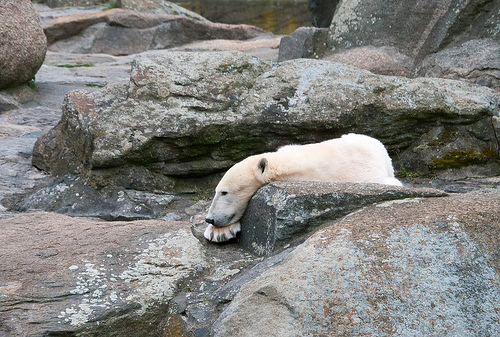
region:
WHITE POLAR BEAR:
[197, 127, 403, 244]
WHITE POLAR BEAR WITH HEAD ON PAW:
[179, 120, 404, 243]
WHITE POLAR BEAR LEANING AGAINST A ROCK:
[199, 131, 402, 246]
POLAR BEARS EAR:
[255, 156, 270, 176]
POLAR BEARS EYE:
[218, 189, 230, 197]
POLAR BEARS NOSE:
[205, 212, 213, 224]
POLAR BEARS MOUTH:
[219, 211, 237, 224]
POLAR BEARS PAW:
[204, 221, 244, 241]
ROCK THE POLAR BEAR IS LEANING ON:
[249, 178, 449, 254]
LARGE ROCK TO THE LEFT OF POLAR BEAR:
[31, 46, 498, 176]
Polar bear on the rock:
[176, 127, 411, 263]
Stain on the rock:
[115, 223, 187, 311]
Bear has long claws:
[202, 201, 255, 253]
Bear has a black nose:
[207, 215, 221, 235]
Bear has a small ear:
[249, 156, 274, 178]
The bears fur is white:
[305, 132, 351, 169]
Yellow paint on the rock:
[257, 10, 302, 36]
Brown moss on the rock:
[350, 220, 414, 293]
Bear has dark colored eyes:
[217, 179, 231, 201]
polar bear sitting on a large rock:
[195, 123, 400, 244]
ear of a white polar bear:
[257, 154, 274, 179]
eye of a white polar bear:
[219, 186, 232, 201]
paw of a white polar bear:
[202, 218, 243, 245]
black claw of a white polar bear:
[205, 229, 215, 244]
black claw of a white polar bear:
[212, 228, 223, 243]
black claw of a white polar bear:
[220, 231, 229, 242]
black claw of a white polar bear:
[228, 224, 237, 237]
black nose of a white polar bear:
[205, 215, 214, 225]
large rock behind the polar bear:
[25, 38, 493, 185]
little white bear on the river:
[199, 132, 409, 239]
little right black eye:
[220, 186, 230, 196]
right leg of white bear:
[201, 218, 241, 245]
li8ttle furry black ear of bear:
[258, 156, 273, 176]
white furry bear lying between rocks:
[205, 128, 400, 248]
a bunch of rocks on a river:
[0, 3, 497, 333]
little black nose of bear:
[199, 212, 215, 225]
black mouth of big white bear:
[210, 211, 236, 228]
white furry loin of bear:
[272, 128, 384, 190]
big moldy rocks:
[6, 2, 496, 334]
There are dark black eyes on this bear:
[215, 176, 235, 201]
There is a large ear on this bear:
[251, 143, 275, 189]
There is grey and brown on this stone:
[366, 249, 402, 318]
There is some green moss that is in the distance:
[255, 9, 294, 36]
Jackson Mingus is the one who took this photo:
[81, 26, 330, 320]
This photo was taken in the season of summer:
[61, 60, 293, 304]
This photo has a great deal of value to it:
[64, 58, 325, 330]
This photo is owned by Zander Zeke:
[77, 76, 297, 324]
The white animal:
[185, 115, 412, 272]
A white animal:
[181, 123, 419, 246]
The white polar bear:
[194, 104, 416, 260]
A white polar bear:
[186, 122, 420, 249]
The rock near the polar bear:
[32, 41, 496, 171]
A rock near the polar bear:
[21, 54, 498, 197]